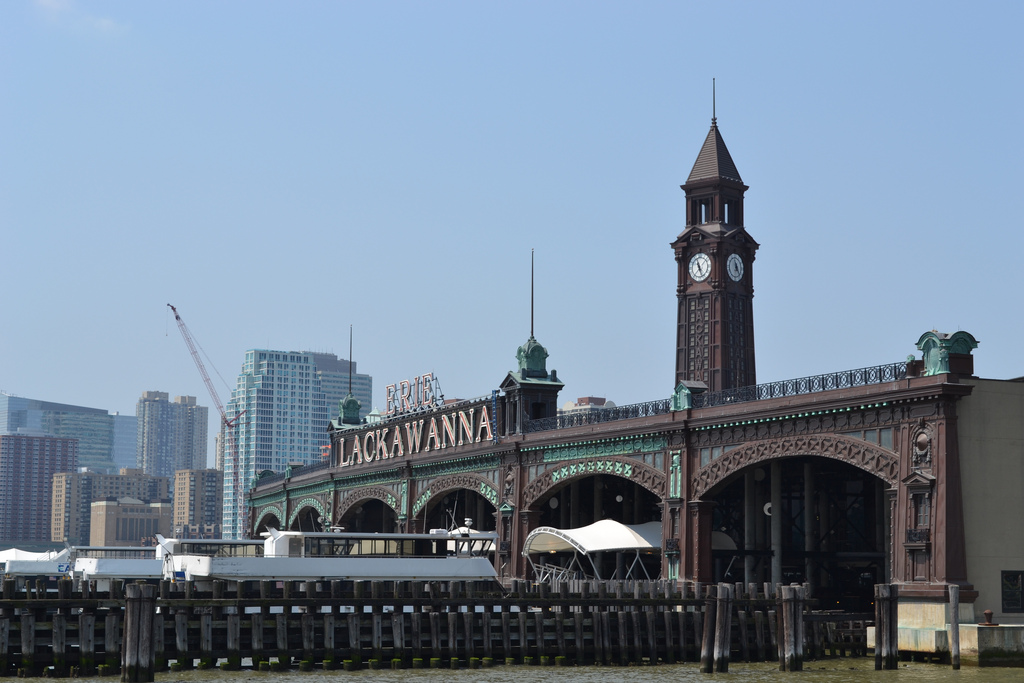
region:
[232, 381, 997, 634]
a large structure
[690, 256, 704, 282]
a clock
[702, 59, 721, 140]
very top of the tower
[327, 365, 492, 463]
the sign on the structure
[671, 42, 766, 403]
a clock tower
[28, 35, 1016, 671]
a scene of downtown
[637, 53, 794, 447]
a clock tower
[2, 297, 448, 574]
buildings in the background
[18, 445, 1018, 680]
a port in the water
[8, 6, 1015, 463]
a blue sky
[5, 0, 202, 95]
a white cloud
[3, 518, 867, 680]
some wooden posts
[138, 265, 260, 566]
a crane in the background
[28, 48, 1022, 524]
a scene outside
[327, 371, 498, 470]
Name on a bridge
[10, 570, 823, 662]
Fence made of wood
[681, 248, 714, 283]
Clock on a tower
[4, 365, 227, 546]
Group of large buildings in the background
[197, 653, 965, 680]
Water by a bridge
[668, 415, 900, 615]
Openings on a bridge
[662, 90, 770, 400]
Tower with a clock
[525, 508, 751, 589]
Boat under a bridge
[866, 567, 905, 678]
Wood posts in the water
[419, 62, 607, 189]
Large body of blue skies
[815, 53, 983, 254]
Large body of blue skies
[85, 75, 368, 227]
Large body of blue skies